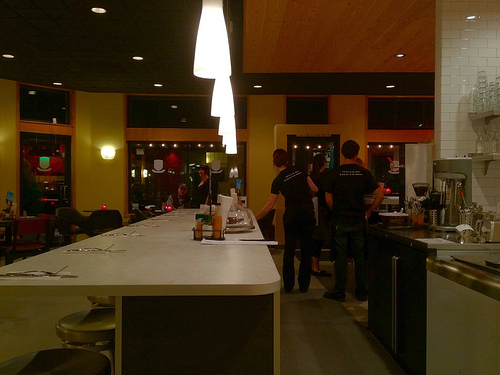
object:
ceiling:
[0, 0, 436, 96]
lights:
[131, 56, 145, 62]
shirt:
[322, 163, 379, 225]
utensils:
[0, 264, 79, 278]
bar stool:
[55, 306, 116, 355]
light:
[100, 145, 116, 160]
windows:
[17, 84, 74, 126]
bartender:
[323, 140, 386, 303]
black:
[335, 191, 357, 216]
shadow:
[278, 299, 368, 325]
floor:
[266, 248, 399, 374]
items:
[193, 183, 256, 254]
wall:
[75, 91, 126, 216]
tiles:
[457, 66, 481, 75]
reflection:
[457, 10, 480, 65]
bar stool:
[6, 345, 116, 374]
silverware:
[67, 243, 115, 252]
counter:
[0, 208, 284, 296]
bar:
[0, 208, 282, 375]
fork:
[5, 264, 70, 277]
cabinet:
[366, 235, 429, 373]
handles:
[394, 257, 400, 354]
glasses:
[472, 69, 499, 115]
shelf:
[470, 109, 499, 122]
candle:
[101, 204, 107, 210]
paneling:
[241, 0, 435, 72]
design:
[152, 159, 166, 174]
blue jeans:
[330, 223, 369, 298]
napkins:
[0, 271, 70, 280]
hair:
[341, 139, 360, 159]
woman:
[255, 148, 319, 293]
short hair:
[273, 148, 291, 167]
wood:
[246, 10, 310, 63]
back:
[322, 163, 381, 225]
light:
[89, 6, 107, 14]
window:
[127, 140, 247, 212]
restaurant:
[0, 0, 500, 375]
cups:
[242, 199, 246, 208]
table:
[0, 215, 59, 242]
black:
[295, 190, 312, 212]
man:
[166, 183, 193, 211]